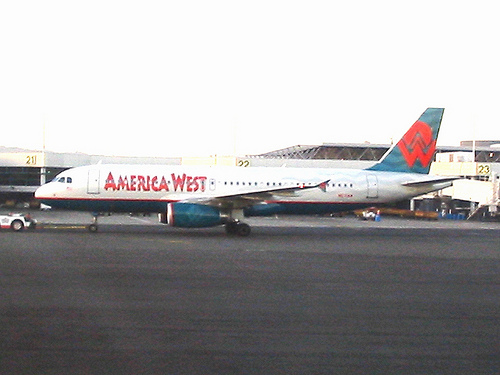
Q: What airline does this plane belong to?
A: America West.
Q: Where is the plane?
A: On the tarmac.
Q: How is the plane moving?
A: It is being towed.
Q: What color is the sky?
A: White.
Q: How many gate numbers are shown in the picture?
A: Three.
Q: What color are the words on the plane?
A: Red.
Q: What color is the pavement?
A: Grey.